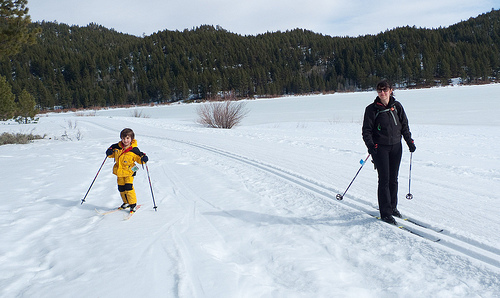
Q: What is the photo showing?
A: It is showing a field.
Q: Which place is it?
A: It is a field.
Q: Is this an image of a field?
A: Yes, it is showing a field.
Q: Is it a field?
A: Yes, it is a field.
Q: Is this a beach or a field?
A: It is a field.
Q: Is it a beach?
A: No, it is a field.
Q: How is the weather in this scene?
A: It is cloudy.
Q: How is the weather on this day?
A: It is cloudy.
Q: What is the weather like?
A: It is cloudy.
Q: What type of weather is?
A: It is cloudy.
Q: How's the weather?
A: It is cloudy.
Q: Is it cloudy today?
A: Yes, it is cloudy.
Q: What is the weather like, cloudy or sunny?
A: It is cloudy.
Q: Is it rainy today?
A: No, it is cloudy.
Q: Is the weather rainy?
A: No, it is cloudy.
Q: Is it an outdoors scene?
A: Yes, it is outdoors.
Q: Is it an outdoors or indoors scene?
A: It is outdoors.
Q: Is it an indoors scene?
A: No, it is outdoors.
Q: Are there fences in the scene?
A: No, there are no fences.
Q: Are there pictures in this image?
A: No, there are no pictures.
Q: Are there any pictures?
A: No, there are no pictures.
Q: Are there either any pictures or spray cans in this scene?
A: No, there are no pictures or spray cans.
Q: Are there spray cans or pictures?
A: No, there are no pictures or spray cans.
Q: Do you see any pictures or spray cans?
A: No, there are no pictures or spray cans.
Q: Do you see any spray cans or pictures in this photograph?
A: No, there are no pictures or spray cans.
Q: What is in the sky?
A: The clouds are in the sky.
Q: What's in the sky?
A: The clouds are in the sky.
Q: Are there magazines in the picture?
A: No, there are no magazines.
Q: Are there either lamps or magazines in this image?
A: No, there are no magazines or lamps.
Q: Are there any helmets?
A: No, there are no helmets.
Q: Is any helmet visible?
A: No, there are no helmets.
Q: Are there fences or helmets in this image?
A: No, there are no helmets or fences.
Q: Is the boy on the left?
A: Yes, the boy is on the left of the image.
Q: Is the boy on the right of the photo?
A: No, the boy is on the left of the image.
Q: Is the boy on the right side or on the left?
A: The boy is on the left of the image.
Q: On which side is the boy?
A: The boy is on the left of the image.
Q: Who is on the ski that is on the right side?
A: The boy is on the ski.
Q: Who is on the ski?
A: The boy is on the ski.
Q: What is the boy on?
A: The boy is on the ski.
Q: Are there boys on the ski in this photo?
A: Yes, there is a boy on the ski.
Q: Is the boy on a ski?
A: Yes, the boy is on a ski.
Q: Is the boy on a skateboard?
A: No, the boy is on a ski.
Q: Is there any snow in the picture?
A: Yes, there is snow.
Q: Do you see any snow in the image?
A: Yes, there is snow.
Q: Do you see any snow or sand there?
A: Yes, there is snow.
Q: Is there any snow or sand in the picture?
A: Yes, there is snow.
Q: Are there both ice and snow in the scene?
A: No, there is snow but no ice.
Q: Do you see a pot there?
A: No, there are no pots.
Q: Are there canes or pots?
A: No, there are no pots or canes.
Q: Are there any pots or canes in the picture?
A: No, there are no pots or canes.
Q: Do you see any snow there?
A: Yes, there is snow.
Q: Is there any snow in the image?
A: Yes, there is snow.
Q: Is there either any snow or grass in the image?
A: Yes, there is snow.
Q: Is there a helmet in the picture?
A: No, there are no helmets.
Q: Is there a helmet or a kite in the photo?
A: No, there are no helmets or kites.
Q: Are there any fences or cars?
A: No, there are no fences or cars.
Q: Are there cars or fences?
A: No, there are no fences or cars.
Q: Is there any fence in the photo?
A: No, there are no fences.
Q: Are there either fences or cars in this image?
A: No, there are no fences or cars.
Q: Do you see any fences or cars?
A: No, there are no fences or cars.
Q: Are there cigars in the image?
A: No, there are no cigars.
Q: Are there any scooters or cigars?
A: No, there are no cigars or scooters.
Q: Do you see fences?
A: No, there are no fences.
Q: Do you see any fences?
A: No, there are no fences.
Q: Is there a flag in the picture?
A: No, there are no flags.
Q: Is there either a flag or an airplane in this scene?
A: No, there are no flags or airplanes.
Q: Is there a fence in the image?
A: No, there are no fences.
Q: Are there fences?
A: No, there are no fences.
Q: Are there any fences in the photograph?
A: No, there are no fences.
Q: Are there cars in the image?
A: No, there are no cars.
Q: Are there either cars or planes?
A: No, there are no cars or planes.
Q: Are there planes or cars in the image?
A: No, there are no cars or planes.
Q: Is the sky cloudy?
A: Yes, the sky is cloudy.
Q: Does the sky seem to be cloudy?
A: Yes, the sky is cloudy.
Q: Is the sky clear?
A: No, the sky is cloudy.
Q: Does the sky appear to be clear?
A: No, the sky is cloudy.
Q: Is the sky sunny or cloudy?
A: The sky is cloudy.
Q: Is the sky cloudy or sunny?
A: The sky is cloudy.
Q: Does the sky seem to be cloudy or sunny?
A: The sky is cloudy.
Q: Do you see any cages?
A: No, there are no cages.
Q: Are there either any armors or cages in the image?
A: No, there are no cages or armors.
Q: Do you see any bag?
A: No, there are no bags.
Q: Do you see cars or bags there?
A: No, there are no bags or cars.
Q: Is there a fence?
A: No, there are no fences.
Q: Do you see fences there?
A: No, there are no fences.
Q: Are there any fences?
A: No, there are no fences.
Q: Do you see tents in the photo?
A: No, there are no tents.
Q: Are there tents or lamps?
A: No, there are no tents or lamps.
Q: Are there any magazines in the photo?
A: No, there are no magazines.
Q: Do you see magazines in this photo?
A: No, there are no magazines.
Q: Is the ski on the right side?
A: Yes, the ski is on the right of the image.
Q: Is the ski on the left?
A: No, the ski is on the right of the image.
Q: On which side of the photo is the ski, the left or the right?
A: The ski is on the right of the image.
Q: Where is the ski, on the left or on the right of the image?
A: The ski is on the right of the image.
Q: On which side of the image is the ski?
A: The ski is on the right of the image.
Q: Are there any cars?
A: No, there are no cars.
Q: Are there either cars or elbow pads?
A: No, there are no cars or elbow pads.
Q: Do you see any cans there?
A: No, there are no cans.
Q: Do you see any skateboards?
A: No, there are no skateboards.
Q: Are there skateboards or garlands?
A: No, there are no skateboards or garlands.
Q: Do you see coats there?
A: Yes, there is a coat.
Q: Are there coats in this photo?
A: Yes, there is a coat.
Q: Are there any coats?
A: Yes, there is a coat.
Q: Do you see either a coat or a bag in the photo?
A: Yes, there is a coat.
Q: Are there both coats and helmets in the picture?
A: No, there is a coat but no helmets.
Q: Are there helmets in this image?
A: No, there are no helmets.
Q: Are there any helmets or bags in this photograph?
A: No, there are no helmets or bags.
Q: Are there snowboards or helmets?
A: No, there are no helmets or snowboards.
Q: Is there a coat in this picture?
A: Yes, there is a coat.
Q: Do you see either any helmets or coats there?
A: Yes, there is a coat.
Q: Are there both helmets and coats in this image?
A: No, there is a coat but no helmets.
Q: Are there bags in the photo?
A: No, there are no bags.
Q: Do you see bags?
A: No, there are no bags.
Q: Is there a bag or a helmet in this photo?
A: No, there are no bags or helmets.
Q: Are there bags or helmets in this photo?
A: No, there are no bags or helmets.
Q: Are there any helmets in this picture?
A: No, there are no helmets.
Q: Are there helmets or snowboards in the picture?
A: No, there are no helmets or snowboards.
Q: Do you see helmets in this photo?
A: No, there are no helmets.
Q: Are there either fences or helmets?
A: No, there are no helmets or fences.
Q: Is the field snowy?
A: Yes, the field is snowy.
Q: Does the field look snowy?
A: Yes, the field is snowy.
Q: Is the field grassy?
A: No, the field is snowy.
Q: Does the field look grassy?
A: No, the field is snowy.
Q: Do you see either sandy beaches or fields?
A: No, there is a field but it is snowy.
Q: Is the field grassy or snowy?
A: The field is snowy.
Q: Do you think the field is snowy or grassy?
A: The field is snowy.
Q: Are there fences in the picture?
A: No, there are no fences.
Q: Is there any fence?
A: No, there are no fences.